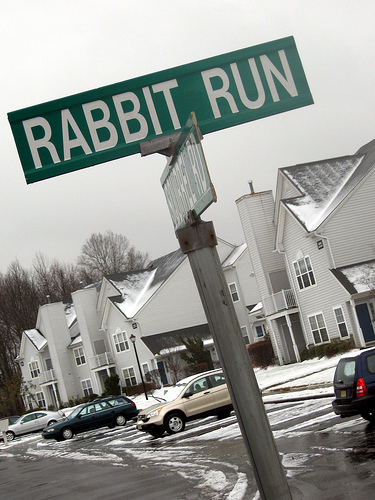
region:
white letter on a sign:
[258, 43, 300, 108]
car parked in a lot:
[135, 363, 240, 449]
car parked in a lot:
[32, 392, 138, 450]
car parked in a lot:
[0, 404, 68, 448]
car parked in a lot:
[330, 340, 373, 431]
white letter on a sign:
[229, 54, 265, 113]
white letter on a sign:
[153, 73, 187, 135]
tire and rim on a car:
[163, 405, 185, 436]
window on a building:
[109, 326, 129, 356]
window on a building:
[302, 306, 332, 351]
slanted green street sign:
[6, 31, 318, 189]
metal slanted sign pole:
[173, 227, 295, 499]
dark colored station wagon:
[42, 393, 138, 436]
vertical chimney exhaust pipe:
[246, 176, 255, 193]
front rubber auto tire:
[160, 413, 188, 433]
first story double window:
[302, 309, 329, 345]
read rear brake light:
[355, 377, 363, 397]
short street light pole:
[128, 329, 148, 400]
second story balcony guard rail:
[87, 352, 113, 372]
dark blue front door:
[348, 300, 373, 341]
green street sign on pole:
[38, 79, 294, 123]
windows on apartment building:
[289, 259, 314, 289]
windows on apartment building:
[305, 312, 329, 344]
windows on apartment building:
[331, 309, 350, 341]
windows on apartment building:
[112, 334, 128, 350]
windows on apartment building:
[120, 368, 136, 385]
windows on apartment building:
[69, 349, 82, 365]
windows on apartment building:
[78, 378, 93, 394]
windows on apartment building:
[25, 361, 42, 378]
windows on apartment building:
[34, 391, 53, 405]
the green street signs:
[1, 36, 316, 224]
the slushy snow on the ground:
[29, 438, 231, 498]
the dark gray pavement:
[17, 471, 124, 498]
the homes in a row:
[20, 242, 371, 394]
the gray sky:
[13, 15, 169, 67]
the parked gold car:
[133, 362, 235, 447]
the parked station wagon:
[41, 393, 135, 440]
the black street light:
[124, 328, 148, 405]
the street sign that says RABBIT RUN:
[13, 34, 301, 175]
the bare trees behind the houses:
[1, 229, 147, 444]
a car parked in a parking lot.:
[121, 365, 251, 457]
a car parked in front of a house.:
[36, 378, 147, 457]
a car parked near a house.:
[323, 322, 373, 428]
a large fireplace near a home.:
[30, 289, 92, 407]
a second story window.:
[111, 323, 131, 357]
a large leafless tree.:
[76, 228, 154, 290]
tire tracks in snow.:
[11, 437, 258, 498]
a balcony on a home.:
[257, 277, 295, 321]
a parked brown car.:
[133, 358, 259, 442]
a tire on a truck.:
[166, 400, 184, 445]